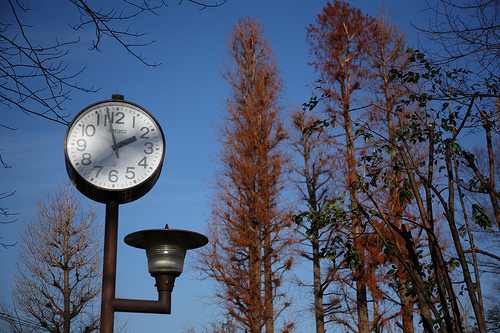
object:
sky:
[0, 0, 499, 333]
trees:
[193, 11, 291, 333]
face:
[68, 105, 161, 191]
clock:
[62, 92, 166, 204]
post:
[97, 200, 116, 332]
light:
[112, 222, 208, 316]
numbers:
[107, 167, 117, 182]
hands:
[110, 134, 140, 149]